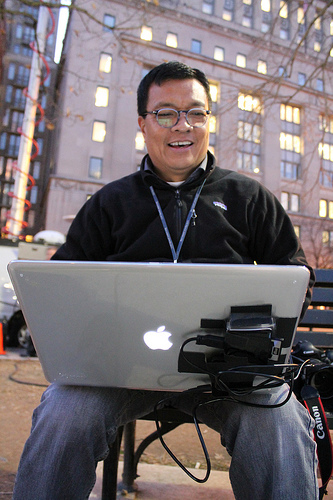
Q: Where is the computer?
A: On persons lap.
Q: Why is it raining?
A: It isn't.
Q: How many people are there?
A: One.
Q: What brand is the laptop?
A: Apple.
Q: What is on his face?
A: Glasses.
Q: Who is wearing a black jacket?
A: Man in picture.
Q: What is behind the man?
A: A building.